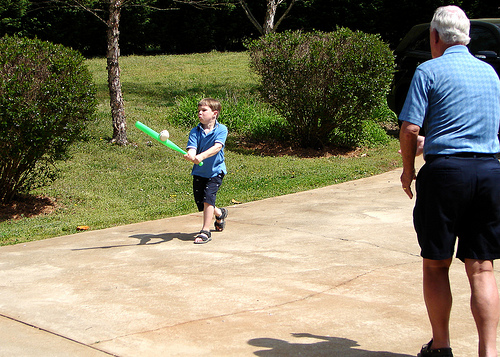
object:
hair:
[199, 98, 223, 113]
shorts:
[192, 170, 225, 213]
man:
[398, 7, 500, 357]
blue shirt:
[399, 44, 500, 155]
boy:
[186, 98, 228, 244]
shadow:
[259, 335, 398, 357]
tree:
[0, 0, 237, 152]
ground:
[73, 164, 88, 196]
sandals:
[213, 207, 228, 232]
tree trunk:
[106, 1, 126, 149]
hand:
[400, 167, 420, 198]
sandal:
[195, 230, 212, 244]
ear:
[431, 27, 441, 44]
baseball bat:
[134, 120, 204, 166]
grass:
[99, 176, 144, 199]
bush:
[243, 30, 398, 142]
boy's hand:
[183, 151, 196, 160]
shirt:
[185, 119, 229, 178]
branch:
[79, 5, 108, 25]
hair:
[433, 5, 472, 43]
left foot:
[193, 229, 212, 244]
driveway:
[19, 150, 403, 357]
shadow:
[128, 231, 201, 246]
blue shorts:
[412, 154, 500, 261]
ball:
[159, 128, 169, 141]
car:
[388, 17, 499, 113]